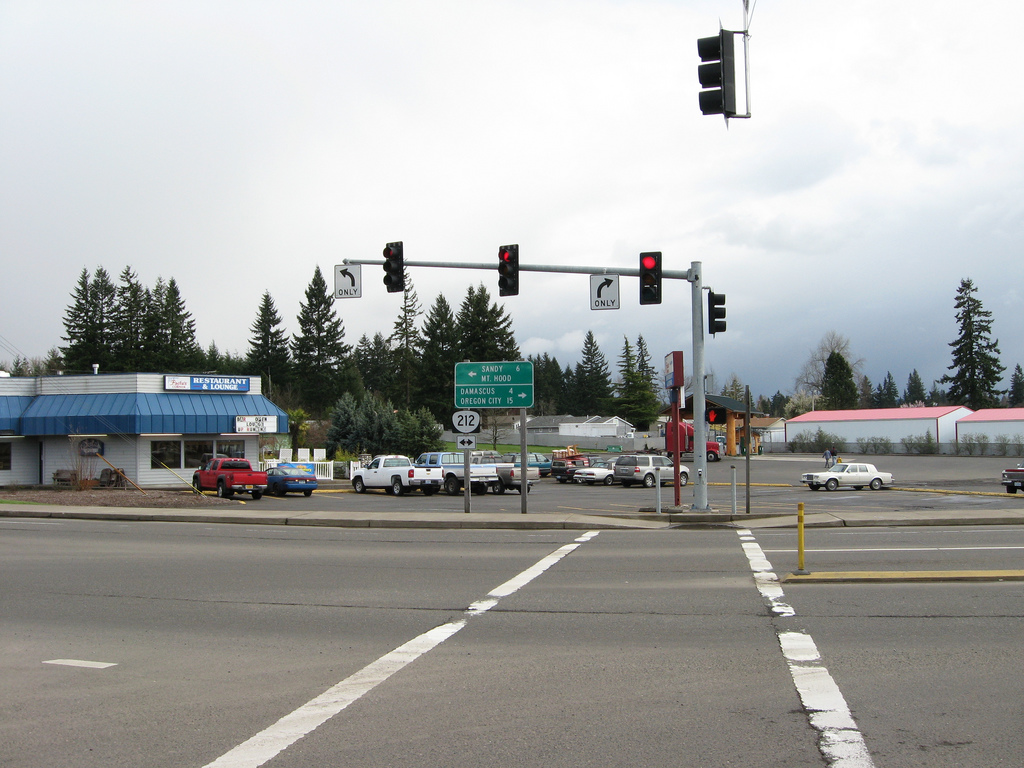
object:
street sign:
[454, 361, 534, 514]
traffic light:
[334, 241, 726, 511]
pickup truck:
[192, 457, 268, 500]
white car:
[799, 462, 895, 492]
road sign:
[455, 362, 535, 409]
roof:
[786, 406, 975, 423]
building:
[0, 372, 290, 489]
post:
[521, 408, 527, 516]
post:
[454, 410, 482, 449]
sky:
[0, 0, 1024, 410]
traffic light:
[640, 252, 662, 305]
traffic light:
[498, 244, 519, 296]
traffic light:
[383, 241, 403, 293]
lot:
[0, 449, 1024, 525]